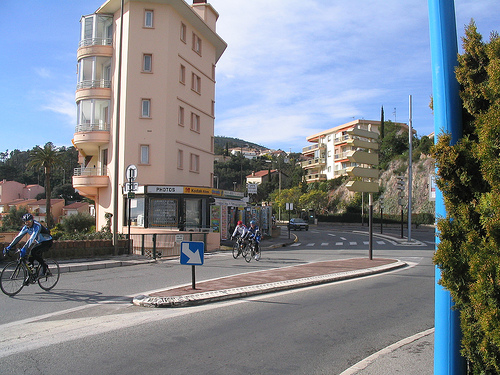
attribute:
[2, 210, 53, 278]
person — riding, bicycling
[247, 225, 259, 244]
clothes — blue, black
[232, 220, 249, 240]
person — riding, bicycling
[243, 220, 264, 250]
person — riding, bicycling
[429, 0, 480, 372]
pole — blue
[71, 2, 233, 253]
building — beige, peach colored, tan, orange, tall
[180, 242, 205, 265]
sign — blue, white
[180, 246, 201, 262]
background — blue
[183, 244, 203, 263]
arrow — white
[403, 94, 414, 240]
pole — grey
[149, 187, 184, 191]
sign — white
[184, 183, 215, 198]
sign — yellow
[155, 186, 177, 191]
lettering — black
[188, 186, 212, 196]
lettering — black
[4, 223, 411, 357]
paint — white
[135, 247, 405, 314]
sidewalk — brown, paved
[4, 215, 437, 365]
road — paved, gray, grey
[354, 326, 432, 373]
sidewalk — grey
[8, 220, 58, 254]
shirt — blue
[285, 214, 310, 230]
car — driving, grey, four door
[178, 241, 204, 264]
signs — arrow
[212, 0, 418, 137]
clouds — white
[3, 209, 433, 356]
lines — white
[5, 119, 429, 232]
leaves — green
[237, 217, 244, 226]
helmet — red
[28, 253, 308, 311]
shadow — fallig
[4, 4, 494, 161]
sky — blue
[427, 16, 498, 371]
tree — evergreen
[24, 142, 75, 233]
tree — palm